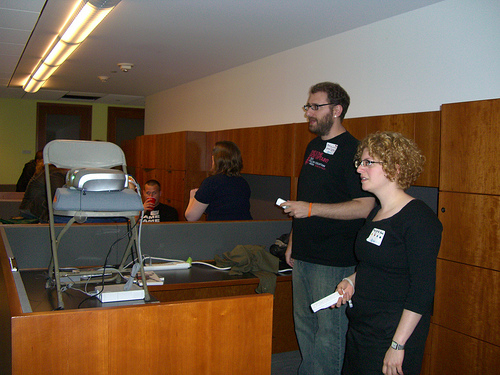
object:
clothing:
[343, 200, 439, 374]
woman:
[349, 132, 445, 374]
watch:
[390, 338, 405, 353]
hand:
[378, 341, 405, 373]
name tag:
[366, 228, 384, 246]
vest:
[354, 194, 436, 325]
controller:
[309, 290, 348, 313]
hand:
[335, 277, 357, 310]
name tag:
[323, 141, 337, 156]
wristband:
[307, 203, 312, 217]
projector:
[72, 167, 127, 191]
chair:
[37, 143, 149, 264]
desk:
[0, 273, 275, 375]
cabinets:
[134, 132, 187, 170]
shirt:
[297, 146, 365, 263]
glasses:
[302, 102, 329, 110]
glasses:
[354, 157, 380, 167]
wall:
[153, 115, 294, 183]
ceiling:
[119, 13, 255, 67]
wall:
[383, 26, 469, 91]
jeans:
[279, 259, 352, 374]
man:
[134, 172, 174, 234]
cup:
[144, 195, 159, 207]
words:
[323, 157, 329, 162]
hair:
[384, 138, 420, 185]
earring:
[333, 115, 338, 118]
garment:
[221, 243, 278, 295]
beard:
[318, 114, 333, 137]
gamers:
[287, 81, 376, 275]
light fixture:
[24, 42, 55, 94]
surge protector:
[54, 264, 111, 282]